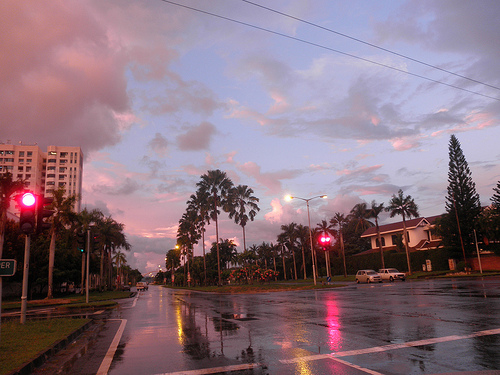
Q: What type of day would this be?
A: Cloudy.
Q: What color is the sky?
A: Blue.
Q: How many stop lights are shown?
A: 2.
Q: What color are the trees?
A: Green.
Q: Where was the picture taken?
A: The outdoors.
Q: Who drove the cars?
A: People.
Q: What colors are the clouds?
A: White, gray and red.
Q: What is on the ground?
A: Rain.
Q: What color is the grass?
A: Green.